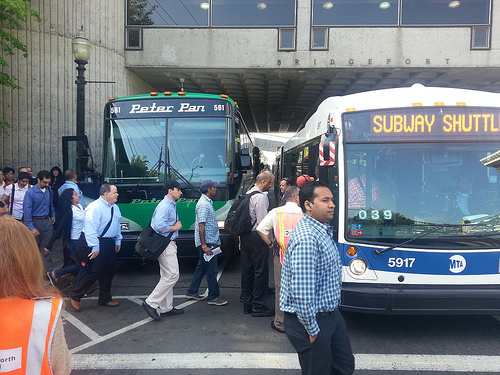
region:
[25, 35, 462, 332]
people in the area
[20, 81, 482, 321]
these people are boarding a bus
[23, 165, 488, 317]
these people might be office workers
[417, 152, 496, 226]
this is the bus driver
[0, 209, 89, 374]
this is a worker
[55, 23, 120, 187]
this is a lampole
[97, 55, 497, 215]
these are two buses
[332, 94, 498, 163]
this is the bus's route sign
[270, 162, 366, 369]
this man is wearing a checkered shirt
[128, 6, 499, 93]
this is a part of a building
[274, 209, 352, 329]
A man in a checkered shirt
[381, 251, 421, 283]
Number 5917 painted on front of bus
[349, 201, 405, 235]
Number 039 on window of bus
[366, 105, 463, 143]
orange lighted sign on front of bus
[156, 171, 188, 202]
A man wearing a black hat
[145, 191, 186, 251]
A man wearing a blue shirt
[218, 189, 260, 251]
A man wearing a black backpack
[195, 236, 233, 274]
A man holding a white paper in his hand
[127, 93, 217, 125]
A Peter Pan sign on the top of a bus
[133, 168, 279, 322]
Three people boarding a bus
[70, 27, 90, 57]
A lamp above a bus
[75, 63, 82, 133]
A blackish lamp pole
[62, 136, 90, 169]
Driver door of bus open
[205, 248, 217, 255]
A piece of paper in the hand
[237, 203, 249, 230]
A black back pack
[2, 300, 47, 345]
A woman in a reflective jacket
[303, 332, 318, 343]
A man with hand in the pocket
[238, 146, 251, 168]
A bus black side mirror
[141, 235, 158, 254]
A shoulder strapped bag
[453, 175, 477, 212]
Bus driver behind the wheel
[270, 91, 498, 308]
A large white bus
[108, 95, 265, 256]
A large green bus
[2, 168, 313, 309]
A line of people boarding a bus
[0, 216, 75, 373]
A safety guard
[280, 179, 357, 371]
Man in a blue checkered shirt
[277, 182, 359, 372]
A man with his hands in his pockets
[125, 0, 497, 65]
A buildings overpass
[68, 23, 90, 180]
A tall lampost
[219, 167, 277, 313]
A man with a backpack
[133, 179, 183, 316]
A man wearing white pants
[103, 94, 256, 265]
a green and black bus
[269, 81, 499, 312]
a white and blue bus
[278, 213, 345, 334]
blue long sleeve plaid shirt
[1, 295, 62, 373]
an orange and silver wokers vest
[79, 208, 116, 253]
a black bag with a shoulder strap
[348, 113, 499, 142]
digital display reading "Subway Shuttle"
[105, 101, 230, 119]
display reading "Peter Pan"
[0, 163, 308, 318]
people getting off and on buses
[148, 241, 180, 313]
a pair of khakis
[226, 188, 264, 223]
a black bookbag